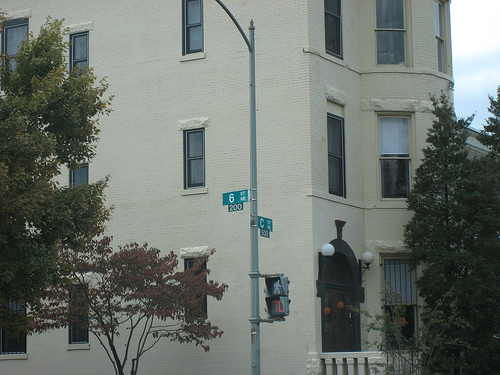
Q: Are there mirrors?
A: No, there are no mirrors.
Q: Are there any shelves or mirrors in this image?
A: No, there are no mirrors or shelves.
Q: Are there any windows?
A: Yes, there is a window.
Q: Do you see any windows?
A: Yes, there is a window.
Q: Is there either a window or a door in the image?
A: Yes, there is a window.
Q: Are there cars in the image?
A: No, there are no cars.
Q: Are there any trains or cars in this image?
A: No, there are no cars or trains.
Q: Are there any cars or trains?
A: No, there are no cars or trains.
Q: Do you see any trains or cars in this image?
A: No, there are no cars or trains.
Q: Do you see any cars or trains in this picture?
A: No, there are no cars or trains.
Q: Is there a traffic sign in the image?
A: Yes, there is a traffic sign.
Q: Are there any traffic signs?
A: Yes, there is a traffic sign.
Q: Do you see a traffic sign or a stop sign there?
A: Yes, there is a traffic sign.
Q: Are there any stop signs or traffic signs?
A: Yes, there is a traffic sign.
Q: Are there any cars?
A: No, there are no cars.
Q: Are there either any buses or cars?
A: No, there are no cars or buses.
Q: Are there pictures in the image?
A: No, there are no pictures.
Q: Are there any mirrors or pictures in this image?
A: No, there are no pictures or mirrors.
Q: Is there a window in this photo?
A: Yes, there is a window.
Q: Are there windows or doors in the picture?
A: Yes, there is a window.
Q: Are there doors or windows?
A: Yes, there is a window.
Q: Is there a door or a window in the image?
A: Yes, there is a window.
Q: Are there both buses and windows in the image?
A: No, there is a window but no buses.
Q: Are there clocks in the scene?
A: No, there are no clocks.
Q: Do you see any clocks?
A: No, there are no clocks.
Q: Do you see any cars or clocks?
A: No, there are no clocks or cars.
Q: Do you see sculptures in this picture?
A: No, there are no sculptures.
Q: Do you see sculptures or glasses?
A: No, there are no sculptures or glasses.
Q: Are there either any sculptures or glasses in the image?
A: No, there are no sculptures or glasses.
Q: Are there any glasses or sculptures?
A: No, there are no sculptures or glasses.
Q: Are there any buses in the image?
A: No, there are no buses.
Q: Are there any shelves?
A: No, there are no shelves.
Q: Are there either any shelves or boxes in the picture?
A: No, there are no shelves or boxes.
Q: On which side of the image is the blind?
A: The blind is on the right of the image.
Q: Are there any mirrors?
A: No, there are no mirrors.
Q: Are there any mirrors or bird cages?
A: No, there are no mirrors or bird cages.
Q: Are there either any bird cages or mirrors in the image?
A: No, there are no mirrors or bird cages.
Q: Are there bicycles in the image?
A: No, there are no bicycles.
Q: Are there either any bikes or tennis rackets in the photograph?
A: No, there are no bikes or tennis rackets.